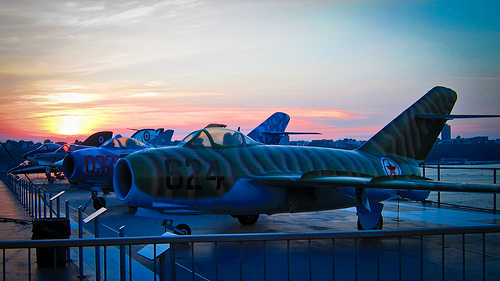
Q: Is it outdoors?
A: Yes, it is outdoors.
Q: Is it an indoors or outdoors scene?
A: It is outdoors.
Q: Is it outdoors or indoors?
A: It is outdoors.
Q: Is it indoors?
A: No, it is outdoors.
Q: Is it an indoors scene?
A: No, it is outdoors.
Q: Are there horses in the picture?
A: No, there are no horses.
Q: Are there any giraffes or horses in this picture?
A: No, there are no horses or giraffes.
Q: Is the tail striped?
A: Yes, the tail is striped.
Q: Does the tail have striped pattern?
A: Yes, the tail is striped.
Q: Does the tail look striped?
A: Yes, the tail is striped.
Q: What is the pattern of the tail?
A: The tail is striped.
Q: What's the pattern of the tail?
A: The tail is striped.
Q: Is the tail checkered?
A: No, the tail is striped.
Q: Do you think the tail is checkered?
A: No, the tail is striped.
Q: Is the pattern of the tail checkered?
A: No, the tail is striped.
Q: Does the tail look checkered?
A: No, the tail is striped.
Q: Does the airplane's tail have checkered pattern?
A: No, the tail is striped.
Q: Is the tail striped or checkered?
A: The tail is striped.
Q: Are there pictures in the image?
A: No, there are no pictures.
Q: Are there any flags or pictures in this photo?
A: No, there are no pictures or flags.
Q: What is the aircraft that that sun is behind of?
A: The aircraft is an airplane.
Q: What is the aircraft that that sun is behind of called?
A: The aircraft is an airplane.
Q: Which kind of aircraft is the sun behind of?
A: The sun is behind the airplane.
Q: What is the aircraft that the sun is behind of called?
A: The aircraft is an airplane.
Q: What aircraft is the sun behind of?
A: The sun is behind the airplane.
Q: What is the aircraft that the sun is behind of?
A: The aircraft is an airplane.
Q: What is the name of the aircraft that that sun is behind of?
A: The aircraft is an airplane.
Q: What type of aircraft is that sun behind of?
A: The sun is behind the plane.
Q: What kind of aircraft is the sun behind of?
A: The sun is behind the plane.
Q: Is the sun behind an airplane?
A: Yes, the sun is behind an airplane.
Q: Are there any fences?
A: Yes, there is a fence.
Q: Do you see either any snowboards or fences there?
A: Yes, there is a fence.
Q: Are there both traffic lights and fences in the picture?
A: No, there is a fence but no traffic lights.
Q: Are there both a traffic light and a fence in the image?
A: No, there is a fence but no traffic lights.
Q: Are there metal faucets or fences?
A: Yes, there is a metal fence.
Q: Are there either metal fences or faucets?
A: Yes, there is a metal fence.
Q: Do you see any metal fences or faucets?
A: Yes, there is a metal fence.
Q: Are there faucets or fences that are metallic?
A: Yes, the fence is metallic.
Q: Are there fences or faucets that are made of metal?
A: Yes, the fence is made of metal.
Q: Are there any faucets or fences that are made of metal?
A: Yes, the fence is made of metal.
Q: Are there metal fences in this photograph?
A: Yes, there is a metal fence.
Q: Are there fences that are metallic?
A: Yes, there is a fence that is metallic.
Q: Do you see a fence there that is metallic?
A: Yes, there is a fence that is metallic.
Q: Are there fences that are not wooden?
A: Yes, there is a metallic fence.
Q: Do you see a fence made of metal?
A: Yes, there is a fence that is made of metal.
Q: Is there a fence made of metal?
A: Yes, there is a fence that is made of metal.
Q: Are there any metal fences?
A: Yes, there is a fence that is made of metal.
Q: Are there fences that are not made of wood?
A: Yes, there is a fence that is made of metal.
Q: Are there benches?
A: No, there are no benches.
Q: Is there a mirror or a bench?
A: No, there are no benches or mirrors.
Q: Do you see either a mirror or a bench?
A: No, there are no benches or mirrors.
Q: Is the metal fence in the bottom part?
A: Yes, the fence is in the bottom of the image.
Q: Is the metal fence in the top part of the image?
A: No, the fence is in the bottom of the image.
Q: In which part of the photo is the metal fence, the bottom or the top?
A: The fence is in the bottom of the image.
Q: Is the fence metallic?
A: Yes, the fence is metallic.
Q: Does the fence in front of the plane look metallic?
A: Yes, the fence is metallic.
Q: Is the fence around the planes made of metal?
A: Yes, the fence is made of metal.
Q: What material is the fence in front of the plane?
A: The fence is made of metal.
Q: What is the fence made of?
A: The fence is made of metal.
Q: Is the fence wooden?
A: No, the fence is metallic.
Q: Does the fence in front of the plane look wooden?
A: No, the fence is metallic.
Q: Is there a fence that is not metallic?
A: No, there is a fence but it is metallic.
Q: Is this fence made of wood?
A: No, the fence is made of metal.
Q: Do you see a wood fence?
A: No, there is a fence but it is made of metal.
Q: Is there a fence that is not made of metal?
A: No, there is a fence but it is made of metal.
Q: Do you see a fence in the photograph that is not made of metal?
A: No, there is a fence but it is made of metal.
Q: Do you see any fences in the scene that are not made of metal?
A: No, there is a fence but it is made of metal.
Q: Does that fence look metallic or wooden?
A: The fence is metallic.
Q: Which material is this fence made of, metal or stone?
A: The fence is made of metal.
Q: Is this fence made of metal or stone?
A: The fence is made of metal.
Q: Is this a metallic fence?
A: Yes, this is a metallic fence.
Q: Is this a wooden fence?
A: No, this is a metallic fence.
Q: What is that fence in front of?
A: The fence is in front of the plane.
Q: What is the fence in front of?
A: The fence is in front of the plane.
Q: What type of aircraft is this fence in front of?
A: The fence is in front of the airplane.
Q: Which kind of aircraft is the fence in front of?
A: The fence is in front of the airplane.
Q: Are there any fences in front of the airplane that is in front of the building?
A: Yes, there is a fence in front of the airplane.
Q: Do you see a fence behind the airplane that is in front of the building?
A: No, the fence is in front of the airplane.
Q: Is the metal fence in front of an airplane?
A: Yes, the fence is in front of an airplane.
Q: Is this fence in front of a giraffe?
A: No, the fence is in front of an airplane.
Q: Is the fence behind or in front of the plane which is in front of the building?
A: The fence is in front of the plane.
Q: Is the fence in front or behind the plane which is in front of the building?
A: The fence is in front of the plane.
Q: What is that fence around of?
A: The fence is around the planes.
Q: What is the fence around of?
A: The fence is around the planes.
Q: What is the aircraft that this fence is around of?
A: The aircraft is airplanes.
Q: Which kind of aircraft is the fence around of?
A: The fence is around the planes.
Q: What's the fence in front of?
A: The fence is in front of the plane.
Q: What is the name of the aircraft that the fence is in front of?
A: The aircraft is an airplane.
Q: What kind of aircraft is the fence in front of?
A: The fence is in front of the plane.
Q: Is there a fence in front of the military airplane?
A: Yes, there is a fence in front of the airplane.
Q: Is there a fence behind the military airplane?
A: No, the fence is in front of the plane.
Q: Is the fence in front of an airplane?
A: Yes, the fence is in front of an airplane.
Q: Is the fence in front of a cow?
A: No, the fence is in front of an airplane.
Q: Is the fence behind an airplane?
A: No, the fence is in front of an airplane.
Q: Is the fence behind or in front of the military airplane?
A: The fence is in front of the airplane.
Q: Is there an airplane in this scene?
A: Yes, there is an airplane.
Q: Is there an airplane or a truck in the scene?
A: Yes, there is an airplane.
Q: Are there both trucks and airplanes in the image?
A: No, there is an airplane but no trucks.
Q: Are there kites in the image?
A: No, there are no kites.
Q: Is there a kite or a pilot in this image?
A: No, there are no kites or pilots.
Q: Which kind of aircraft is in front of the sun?
A: The aircraft is an airplane.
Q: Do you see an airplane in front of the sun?
A: Yes, there is an airplane in front of the sun.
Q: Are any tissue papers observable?
A: No, there are no tissue papers.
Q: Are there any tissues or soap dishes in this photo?
A: No, there are no tissues or soap dishes.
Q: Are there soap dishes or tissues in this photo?
A: No, there are no tissues or soap dishes.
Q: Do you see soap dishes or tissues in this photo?
A: No, there are no tissues or soap dishes.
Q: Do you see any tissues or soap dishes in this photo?
A: No, there are no tissues or soap dishes.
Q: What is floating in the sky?
A: The clouds are floating in the sky.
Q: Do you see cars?
A: No, there are no cars.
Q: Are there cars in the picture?
A: No, there are no cars.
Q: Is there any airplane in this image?
A: Yes, there is an airplane.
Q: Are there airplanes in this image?
A: Yes, there is an airplane.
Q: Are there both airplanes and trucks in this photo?
A: No, there is an airplane but no trucks.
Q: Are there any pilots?
A: No, there are no pilots.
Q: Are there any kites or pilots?
A: No, there are no pilots or kites.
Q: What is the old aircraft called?
A: The aircraft is an airplane.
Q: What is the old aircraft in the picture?
A: The aircraft is an airplane.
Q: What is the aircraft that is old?
A: The aircraft is an airplane.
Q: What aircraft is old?
A: The aircraft is an airplane.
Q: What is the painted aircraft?
A: The aircraft is an airplane.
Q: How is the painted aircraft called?
A: The aircraft is an airplane.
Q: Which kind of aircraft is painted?
A: The aircraft is an airplane.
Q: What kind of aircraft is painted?
A: The aircraft is an airplane.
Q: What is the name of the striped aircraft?
A: The aircraft is an airplane.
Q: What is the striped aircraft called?
A: The aircraft is an airplane.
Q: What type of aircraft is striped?
A: The aircraft is an airplane.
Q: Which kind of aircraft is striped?
A: The aircraft is an airplane.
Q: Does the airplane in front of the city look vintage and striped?
A: Yes, the airplane is vintage and striped.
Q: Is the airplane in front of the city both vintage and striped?
A: Yes, the airplane is vintage and striped.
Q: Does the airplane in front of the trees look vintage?
A: Yes, the airplane is vintage.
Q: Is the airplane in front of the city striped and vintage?
A: Yes, the airplane is striped and vintage.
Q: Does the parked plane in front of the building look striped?
A: Yes, the airplane is striped.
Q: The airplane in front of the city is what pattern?
A: The plane is striped.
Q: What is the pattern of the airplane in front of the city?
A: The plane is striped.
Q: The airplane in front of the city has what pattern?
A: The plane is striped.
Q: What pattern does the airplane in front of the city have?
A: The plane has striped pattern.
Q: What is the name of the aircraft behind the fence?
A: The aircraft is an airplane.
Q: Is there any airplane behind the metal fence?
A: Yes, there is an airplane behind the fence.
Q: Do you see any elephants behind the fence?
A: No, there is an airplane behind the fence.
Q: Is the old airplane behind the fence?
A: Yes, the airplane is behind the fence.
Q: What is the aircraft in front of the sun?
A: The aircraft is an airplane.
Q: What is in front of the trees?
A: The airplane is in front of the trees.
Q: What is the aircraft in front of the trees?
A: The aircraft is an airplane.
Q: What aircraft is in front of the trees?
A: The aircraft is an airplane.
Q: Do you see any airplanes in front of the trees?
A: Yes, there is an airplane in front of the trees.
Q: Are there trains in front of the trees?
A: No, there is an airplane in front of the trees.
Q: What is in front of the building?
A: The airplane is in front of the building.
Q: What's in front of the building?
A: The airplane is in front of the building.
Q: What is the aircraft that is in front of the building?
A: The aircraft is an airplane.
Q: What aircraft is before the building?
A: The aircraft is an airplane.